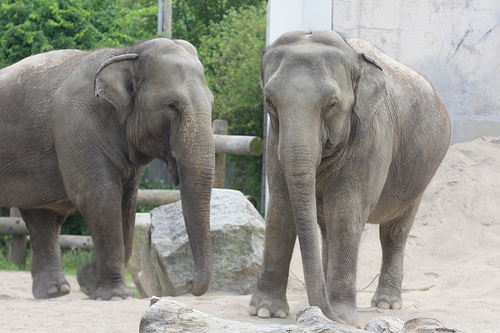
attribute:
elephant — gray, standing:
[0, 37, 216, 298]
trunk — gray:
[172, 124, 217, 296]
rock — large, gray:
[139, 191, 265, 296]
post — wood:
[157, 2, 174, 38]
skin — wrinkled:
[1, 72, 136, 201]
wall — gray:
[270, 0, 499, 141]